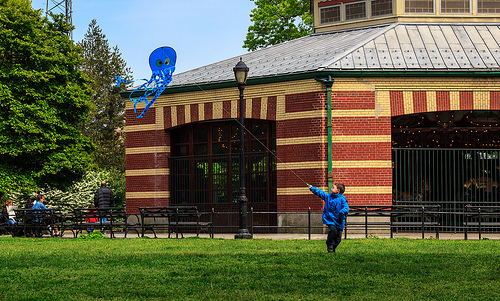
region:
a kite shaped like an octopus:
[113, 43, 178, 121]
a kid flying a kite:
[306, 179, 349, 254]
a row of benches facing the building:
[2, 191, 498, 243]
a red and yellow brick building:
[113, 1, 498, 233]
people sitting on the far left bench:
[3, 192, 61, 235]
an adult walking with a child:
[86, 180, 115, 234]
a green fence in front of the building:
[392, 144, 499, 235]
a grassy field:
[1, 234, 498, 299]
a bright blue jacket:
[308, 184, 349, 226]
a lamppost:
[231, 54, 255, 241]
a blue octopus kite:
[129, 44, 176, 121]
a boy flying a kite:
[306, 180, 348, 253]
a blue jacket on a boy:
[309, 185, 350, 228]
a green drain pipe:
[325, 77, 333, 192]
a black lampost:
[230, 55, 246, 235]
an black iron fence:
[390, 145, 497, 235]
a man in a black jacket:
[91, 177, 111, 207]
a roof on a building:
[117, 21, 494, 87]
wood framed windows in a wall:
[168, 118, 276, 231]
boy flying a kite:
[300, 167, 355, 254]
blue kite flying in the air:
[130, 40, 186, 126]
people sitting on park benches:
[0, 185, 70, 235]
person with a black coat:
[90, 180, 115, 226]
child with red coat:
[85, 201, 100, 223]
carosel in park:
[106, 0, 496, 227]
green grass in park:
[0, 231, 495, 296]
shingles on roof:
[123, 20, 498, 87]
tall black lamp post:
[220, 45, 260, 241]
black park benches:
[0, 200, 220, 240]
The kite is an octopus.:
[125, 42, 181, 114]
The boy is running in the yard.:
[302, 180, 368, 256]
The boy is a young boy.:
[303, 177, 360, 253]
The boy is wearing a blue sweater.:
[304, 173, 356, 258]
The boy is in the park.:
[118, 33, 497, 212]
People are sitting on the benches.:
[8, 174, 245, 249]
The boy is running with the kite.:
[125, 39, 377, 251]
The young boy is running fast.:
[111, 40, 373, 252]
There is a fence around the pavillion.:
[120, 21, 487, 233]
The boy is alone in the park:
[115, 24, 497, 266]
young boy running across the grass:
[304, 180, 366, 256]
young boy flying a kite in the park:
[107, 43, 359, 258]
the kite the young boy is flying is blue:
[111, 36, 188, 121]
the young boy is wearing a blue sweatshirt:
[302, 183, 357, 235]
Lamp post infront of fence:
[229, 57, 258, 245]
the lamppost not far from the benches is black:
[231, 57, 262, 242]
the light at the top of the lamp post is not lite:
[231, 57, 254, 87]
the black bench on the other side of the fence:
[136, 202, 220, 243]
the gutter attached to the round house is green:
[313, 75, 336, 232]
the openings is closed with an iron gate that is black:
[172, 129, 275, 230]